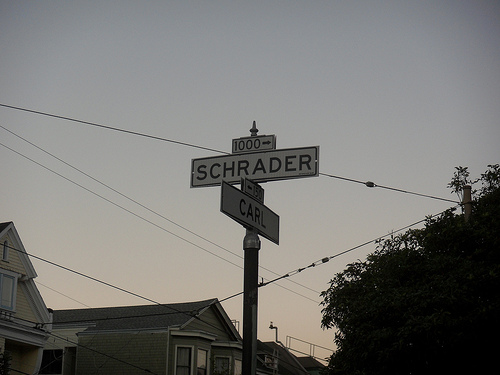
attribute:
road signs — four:
[191, 131, 321, 242]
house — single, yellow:
[0, 220, 54, 372]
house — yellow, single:
[49, 296, 241, 372]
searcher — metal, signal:
[268, 318, 331, 363]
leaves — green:
[392, 328, 474, 375]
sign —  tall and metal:
[222, 176, 281, 197]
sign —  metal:
[201, 149, 300, 208]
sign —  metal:
[219, 158, 291, 182]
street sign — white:
[186, 143, 322, 190]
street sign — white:
[218, 179, 280, 246]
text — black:
[233, 195, 269, 230]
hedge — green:
[313, 167, 483, 373]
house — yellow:
[2, 214, 72, 373]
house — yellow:
[36, 293, 245, 373]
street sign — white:
[188, 139, 323, 186]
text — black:
[197, 151, 313, 182]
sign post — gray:
[240, 229, 264, 372]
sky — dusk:
[2, 0, 483, 340]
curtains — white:
[177, 349, 191, 370]